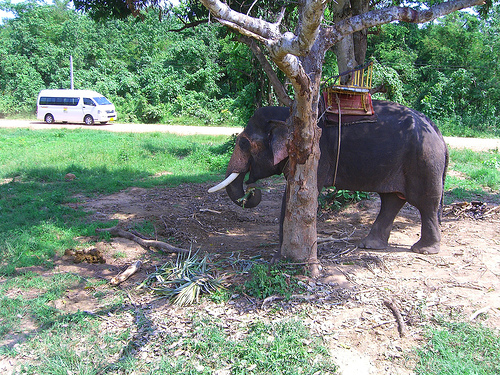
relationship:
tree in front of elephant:
[70, 2, 495, 262] [208, 98, 451, 257]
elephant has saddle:
[208, 98, 451, 257] [319, 61, 376, 119]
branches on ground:
[148, 243, 230, 304] [77, 183, 498, 372]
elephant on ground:
[208, 98, 451, 257] [77, 183, 498, 372]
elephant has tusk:
[208, 98, 451, 257] [204, 168, 240, 196]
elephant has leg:
[208, 98, 451, 257] [406, 182, 444, 260]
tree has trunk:
[70, 2, 495, 262] [272, 57, 322, 275]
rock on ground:
[231, 292, 241, 300] [77, 183, 498, 372]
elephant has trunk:
[208, 98, 451, 257] [222, 170, 263, 211]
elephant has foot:
[208, 98, 451, 257] [410, 239, 442, 258]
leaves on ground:
[248, 262, 303, 300] [77, 183, 498, 372]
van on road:
[35, 86, 119, 127] [1, 117, 500, 152]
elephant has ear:
[208, 98, 451, 257] [269, 115, 292, 169]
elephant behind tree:
[208, 98, 451, 257] [70, 2, 495, 262]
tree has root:
[70, 2, 495, 262] [99, 224, 207, 268]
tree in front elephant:
[70, 2, 495, 262] [208, 98, 451, 257]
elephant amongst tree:
[208, 98, 451, 257] [70, 2, 495, 262]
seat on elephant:
[319, 61, 376, 119] [208, 98, 451, 257]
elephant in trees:
[208, 98, 451, 257] [2, 2, 499, 140]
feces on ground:
[67, 240, 106, 267] [77, 183, 498, 372]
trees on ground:
[148, 243, 230, 304] [77, 183, 498, 372]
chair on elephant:
[319, 61, 376, 119] [208, 98, 451, 257]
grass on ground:
[3, 126, 500, 374] [77, 183, 498, 372]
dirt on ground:
[96, 186, 500, 369] [77, 183, 498, 372]